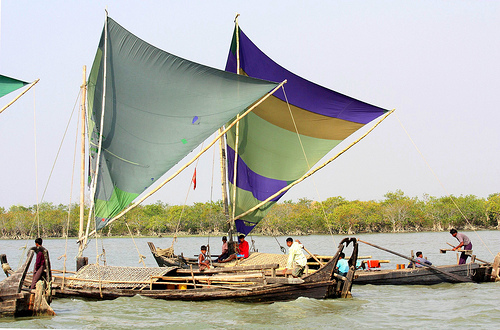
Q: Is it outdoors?
A: Yes, it is outdoors.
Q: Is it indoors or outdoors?
A: It is outdoors.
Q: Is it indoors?
A: No, it is outdoors.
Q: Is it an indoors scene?
A: No, it is outdoors.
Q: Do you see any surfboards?
A: No, there are no surfboards.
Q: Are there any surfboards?
A: No, there are no surfboards.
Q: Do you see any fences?
A: No, there are no fences.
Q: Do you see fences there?
A: No, there are no fences.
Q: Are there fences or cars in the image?
A: No, there are no fences or cars.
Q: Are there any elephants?
A: No, there are no elephants.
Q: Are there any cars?
A: No, there are no cars.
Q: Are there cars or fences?
A: No, there are no cars or fences.